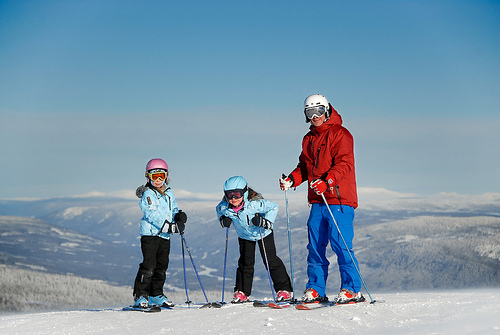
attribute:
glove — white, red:
[267, 169, 341, 199]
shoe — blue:
[130, 295, 157, 309]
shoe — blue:
[146, 293, 167, 307]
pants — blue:
[305, 201, 362, 293]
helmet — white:
[305, 93, 331, 118]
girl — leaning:
[214, 178, 296, 298]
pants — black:
[233, 230, 295, 296]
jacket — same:
[284, 106, 361, 213]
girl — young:
[96, 152, 196, 317]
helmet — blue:
[185, 173, 307, 197]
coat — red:
[296, 108, 360, 207]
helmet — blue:
[230, 176, 258, 191]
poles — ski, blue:
[180, 235, 209, 302]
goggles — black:
[302, 104, 329, 120]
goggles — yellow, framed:
[147, 167, 168, 181]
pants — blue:
[300, 197, 366, 298]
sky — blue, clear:
[10, 12, 483, 145]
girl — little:
[128, 156, 188, 311]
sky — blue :
[1, 0, 499, 199]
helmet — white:
[305, 95, 329, 114]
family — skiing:
[125, 74, 388, 319]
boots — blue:
[122, 287, 178, 307]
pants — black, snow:
[134, 158, 176, 308]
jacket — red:
[299, 114, 403, 221]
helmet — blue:
[222, 173, 247, 192]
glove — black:
[253, 216, 269, 227]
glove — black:
[218, 213, 234, 229]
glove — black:
[174, 210, 189, 233]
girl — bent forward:
[165, 153, 304, 322]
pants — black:
[133, 234, 169, 293]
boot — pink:
[272, 288, 294, 303]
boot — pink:
[230, 289, 250, 301]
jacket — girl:
[209, 195, 284, 240]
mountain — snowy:
[16, 263, 497, 333]